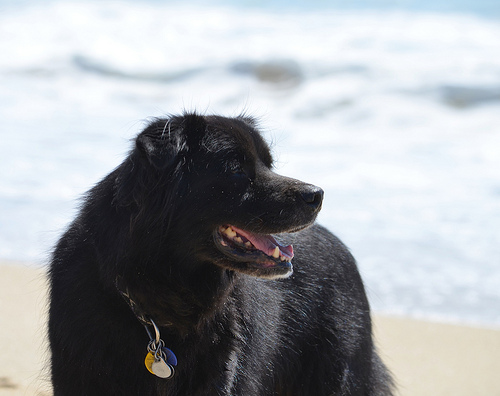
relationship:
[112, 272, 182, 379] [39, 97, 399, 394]
collar on dog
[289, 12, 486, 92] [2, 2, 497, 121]
clouds on sky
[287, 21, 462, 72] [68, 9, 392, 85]
clouds in sky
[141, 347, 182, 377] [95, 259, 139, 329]
charms on chain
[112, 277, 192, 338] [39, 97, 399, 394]
collar on dog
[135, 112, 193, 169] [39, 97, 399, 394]
ear on dog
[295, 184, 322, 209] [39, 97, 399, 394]
nose on dog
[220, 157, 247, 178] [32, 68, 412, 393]
eye on dog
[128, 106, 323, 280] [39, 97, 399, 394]
head of dog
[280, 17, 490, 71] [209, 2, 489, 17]
cloud in sky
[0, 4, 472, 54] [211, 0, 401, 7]
clouds in sky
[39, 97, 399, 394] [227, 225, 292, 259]
dog has tongue